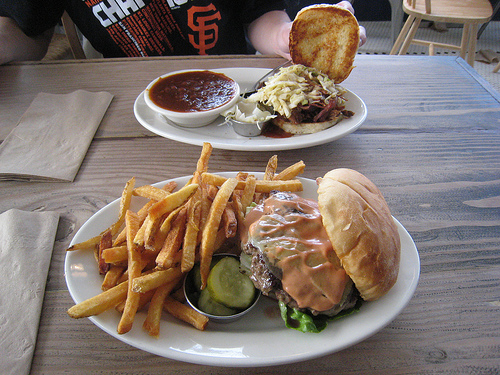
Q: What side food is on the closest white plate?
A: French fries.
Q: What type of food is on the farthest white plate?
A: A pulled pork sandwich, with the top opened.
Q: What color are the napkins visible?
A: Brown.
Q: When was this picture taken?
A: During a mealtime.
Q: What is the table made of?
A: Wood.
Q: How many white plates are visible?
A: Two.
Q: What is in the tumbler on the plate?
A: Pickles.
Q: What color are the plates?
A: White.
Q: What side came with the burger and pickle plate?
A: French fries.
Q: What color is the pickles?
A: Green.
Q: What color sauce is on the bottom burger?
A: Reddish orange.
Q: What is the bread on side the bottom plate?
A: Hamburger bun top.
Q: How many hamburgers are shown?
A: Two.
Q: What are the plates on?
A: Table.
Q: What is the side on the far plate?
A: Chili.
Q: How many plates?
A: 2.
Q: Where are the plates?
A: On table.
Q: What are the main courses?
A: Hamburgers.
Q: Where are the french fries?
A: On nearest plate.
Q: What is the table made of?
A: Wood.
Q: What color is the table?
A: Brown.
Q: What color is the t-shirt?
A: Black.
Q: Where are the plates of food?
A: On a table.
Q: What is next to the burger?
A: Fries.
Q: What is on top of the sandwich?
A: Coleslaw.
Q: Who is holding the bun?
A: A person.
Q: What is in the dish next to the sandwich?
A: Sauce.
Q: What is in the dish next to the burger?
A: Pickles.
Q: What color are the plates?
A: White.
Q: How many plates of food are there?
A: Two.